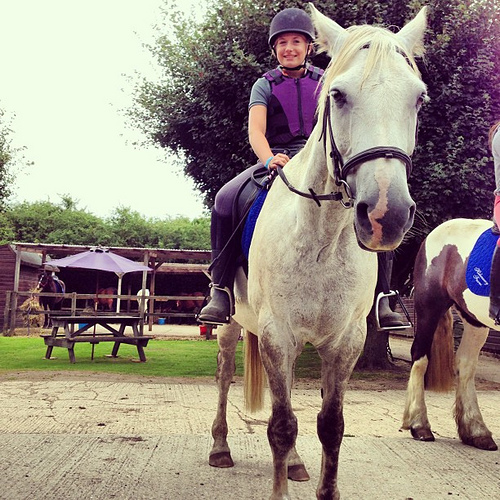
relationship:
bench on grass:
[38, 311, 149, 363] [39, 332, 261, 381]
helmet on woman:
[260, 3, 320, 54] [207, 9, 366, 279]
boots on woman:
[180, 260, 231, 314] [186, 27, 357, 306]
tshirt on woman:
[226, 65, 330, 161] [202, 19, 421, 281]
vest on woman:
[235, 84, 371, 168] [214, 11, 388, 258]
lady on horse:
[192, 8, 324, 326] [226, 55, 480, 418]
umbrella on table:
[40, 227, 190, 314] [34, 295, 169, 370]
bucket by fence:
[178, 310, 258, 345] [105, 261, 242, 348]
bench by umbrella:
[38, 311, 149, 363] [43, 235, 178, 283]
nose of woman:
[287, 38, 298, 52] [196, 36, 435, 340]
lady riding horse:
[192, 8, 324, 326] [164, 60, 481, 460]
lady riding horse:
[192, 8, 324, 326] [161, 36, 431, 450]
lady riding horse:
[192, 39, 423, 352] [164, 60, 481, 460]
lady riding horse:
[192, 8, 324, 326] [135, 58, 463, 454]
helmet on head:
[267, 7, 315, 45] [238, 4, 313, 64]